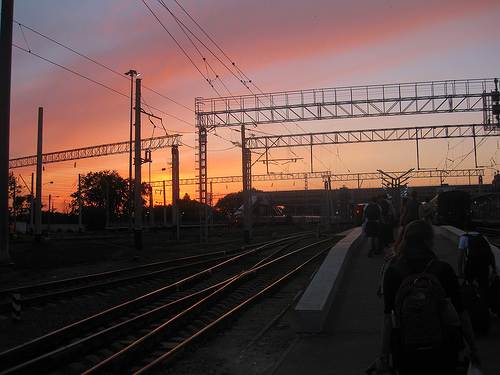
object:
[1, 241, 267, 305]
railroad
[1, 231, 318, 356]
tracks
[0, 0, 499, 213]
sky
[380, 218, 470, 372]
people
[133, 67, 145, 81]
light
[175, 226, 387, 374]
concrete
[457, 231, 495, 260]
shirt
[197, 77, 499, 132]
structure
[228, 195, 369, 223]
train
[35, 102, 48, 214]
pole